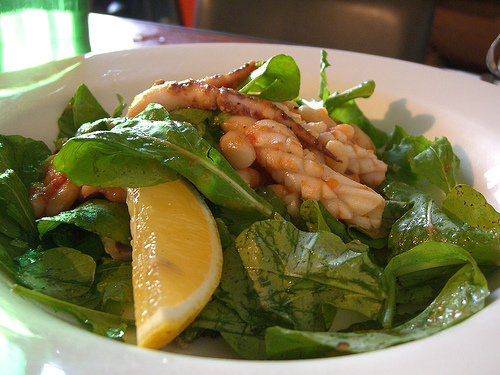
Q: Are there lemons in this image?
A: Yes, there is a lemon.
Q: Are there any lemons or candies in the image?
A: Yes, there is a lemon.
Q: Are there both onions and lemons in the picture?
A: No, there is a lemon but no onions.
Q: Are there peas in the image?
A: No, there are no peas.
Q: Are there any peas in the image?
A: No, there are no peas.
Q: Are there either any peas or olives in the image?
A: No, there are no peas or olives.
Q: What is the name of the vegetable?
A: The vegetable is a lemon.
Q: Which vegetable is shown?
A: The vegetable is a lemon.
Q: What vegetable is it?
A: The vegetable is a lemon.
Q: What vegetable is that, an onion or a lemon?
A: This is a lemon.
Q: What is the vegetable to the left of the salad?
A: The vegetable is a lemon.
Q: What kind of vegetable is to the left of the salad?
A: The vegetable is a lemon.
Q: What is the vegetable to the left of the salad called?
A: The vegetable is a lemon.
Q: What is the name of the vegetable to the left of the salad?
A: The vegetable is a lemon.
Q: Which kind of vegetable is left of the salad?
A: The vegetable is a lemon.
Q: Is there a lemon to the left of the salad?
A: Yes, there is a lemon to the left of the salad.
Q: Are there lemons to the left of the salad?
A: Yes, there is a lemon to the left of the salad.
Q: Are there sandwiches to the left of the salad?
A: No, there is a lemon to the left of the salad.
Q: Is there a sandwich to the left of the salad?
A: No, there is a lemon to the left of the salad.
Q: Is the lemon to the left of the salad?
A: Yes, the lemon is to the left of the salad.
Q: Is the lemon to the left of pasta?
A: No, the lemon is to the left of the salad.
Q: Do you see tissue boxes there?
A: No, there are no tissue boxes.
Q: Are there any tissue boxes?
A: No, there are no tissue boxes.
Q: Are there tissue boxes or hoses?
A: No, there are no tissue boxes or hoses.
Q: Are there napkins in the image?
A: No, there are no napkins.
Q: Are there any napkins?
A: No, there are no napkins.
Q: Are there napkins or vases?
A: No, there are no napkins or vases.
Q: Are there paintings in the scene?
A: No, there are no paintings.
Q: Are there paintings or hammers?
A: No, there are no paintings or hammers.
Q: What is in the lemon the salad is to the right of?
A: The seed is in the lemon.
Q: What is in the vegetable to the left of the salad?
A: The seed is in the lemon.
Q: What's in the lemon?
A: The seed is in the lemon.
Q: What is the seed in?
A: The seed is in the lemon.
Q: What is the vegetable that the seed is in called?
A: The vegetable is a lemon.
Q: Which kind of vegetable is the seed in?
A: The seed is in the lemon.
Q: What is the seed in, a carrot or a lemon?
A: The seed is in a lemon.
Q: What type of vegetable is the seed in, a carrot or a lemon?
A: The seed is in a lemon.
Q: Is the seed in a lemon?
A: Yes, the seed is in a lemon.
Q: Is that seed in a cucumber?
A: No, the seed is in a lemon.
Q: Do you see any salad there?
A: Yes, there is salad.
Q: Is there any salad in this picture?
A: Yes, there is salad.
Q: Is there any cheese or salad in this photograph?
A: Yes, there is salad.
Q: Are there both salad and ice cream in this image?
A: No, there is salad but no ice cream.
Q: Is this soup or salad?
A: This is salad.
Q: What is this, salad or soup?
A: This is salad.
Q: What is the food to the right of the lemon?
A: The food is salad.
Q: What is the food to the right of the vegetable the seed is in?
A: The food is salad.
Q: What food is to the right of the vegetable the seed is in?
A: The food is salad.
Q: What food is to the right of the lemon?
A: The food is salad.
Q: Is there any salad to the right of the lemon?
A: Yes, there is salad to the right of the lemon.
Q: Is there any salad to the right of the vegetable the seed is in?
A: Yes, there is salad to the right of the lemon.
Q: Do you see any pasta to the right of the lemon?
A: No, there is salad to the right of the lemon.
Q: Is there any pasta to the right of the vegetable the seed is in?
A: No, there is salad to the right of the lemon.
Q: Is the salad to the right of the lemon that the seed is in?
A: Yes, the salad is to the right of the lemon.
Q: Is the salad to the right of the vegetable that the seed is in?
A: Yes, the salad is to the right of the lemon.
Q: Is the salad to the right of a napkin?
A: No, the salad is to the right of the lemon.